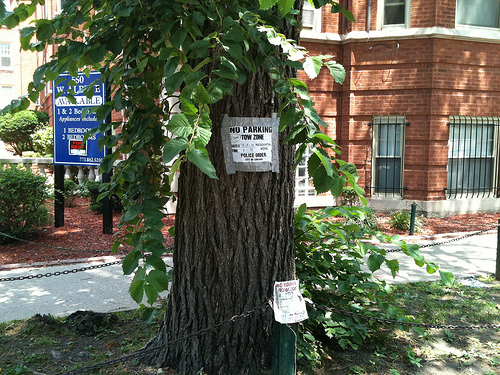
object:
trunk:
[171, 48, 292, 342]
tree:
[78, 6, 309, 374]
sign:
[212, 111, 290, 180]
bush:
[294, 196, 375, 343]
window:
[362, 113, 407, 201]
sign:
[49, 71, 110, 170]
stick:
[45, 164, 75, 228]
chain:
[95, 295, 270, 352]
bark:
[247, 80, 273, 110]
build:
[343, 2, 496, 212]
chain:
[3, 256, 116, 287]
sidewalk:
[5, 261, 149, 309]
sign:
[67, 138, 90, 157]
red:
[390, 69, 432, 90]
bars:
[391, 112, 400, 199]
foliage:
[158, 6, 214, 180]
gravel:
[423, 222, 440, 232]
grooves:
[186, 187, 199, 223]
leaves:
[142, 173, 154, 203]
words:
[72, 141, 76, 144]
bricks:
[378, 73, 394, 80]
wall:
[353, 52, 380, 57]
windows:
[449, 109, 500, 161]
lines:
[340, 15, 433, 51]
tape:
[218, 110, 283, 132]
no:
[227, 125, 276, 165]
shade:
[366, 51, 474, 109]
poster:
[271, 277, 316, 327]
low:
[263, 265, 325, 375]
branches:
[111, 11, 169, 295]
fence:
[8, 262, 191, 366]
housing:
[51, 62, 118, 235]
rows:
[347, 45, 438, 67]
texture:
[264, 238, 279, 264]